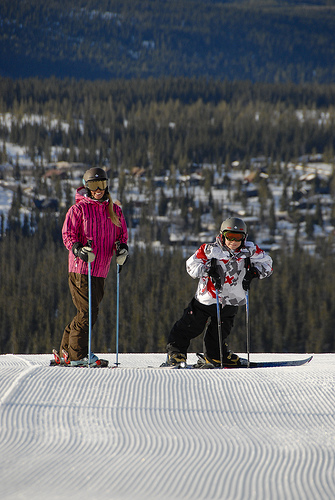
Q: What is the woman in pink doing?
A: Skiing.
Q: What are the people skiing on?
A: Snow.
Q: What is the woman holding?
A: Poles.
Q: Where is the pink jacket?
A: On the girl.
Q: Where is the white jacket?
A: On the boy.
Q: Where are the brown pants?
A: On the girl.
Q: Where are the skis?
A: In the snow.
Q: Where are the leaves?
A: On the trees.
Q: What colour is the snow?
A: White.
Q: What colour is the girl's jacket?
A: Pink.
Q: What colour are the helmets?
A: Gray.